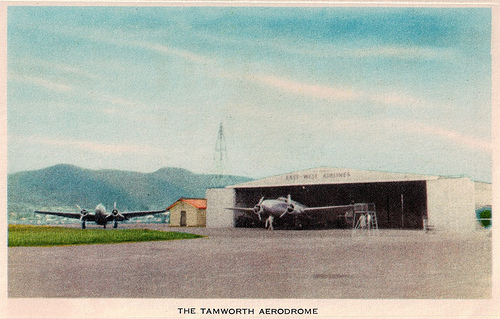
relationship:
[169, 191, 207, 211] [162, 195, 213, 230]
roof on building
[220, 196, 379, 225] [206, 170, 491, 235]
plane in hanger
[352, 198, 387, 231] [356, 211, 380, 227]
ladder by people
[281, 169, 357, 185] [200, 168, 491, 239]
letters are on hangar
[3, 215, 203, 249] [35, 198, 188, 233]
grass in front of plane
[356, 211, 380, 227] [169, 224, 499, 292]
people are on runway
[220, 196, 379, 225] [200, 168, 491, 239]
plane in hangar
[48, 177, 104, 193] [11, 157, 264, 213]
trees are on hills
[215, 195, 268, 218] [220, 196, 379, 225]
left wing on plane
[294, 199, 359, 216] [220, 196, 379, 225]
right wing on plane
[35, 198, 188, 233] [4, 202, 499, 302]
plane on runway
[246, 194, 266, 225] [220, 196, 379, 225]
propeller blade on plane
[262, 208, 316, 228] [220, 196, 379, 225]
underside of plane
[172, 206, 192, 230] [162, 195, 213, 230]
door on building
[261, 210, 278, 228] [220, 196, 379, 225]
person under plane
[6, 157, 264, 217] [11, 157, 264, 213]
hills in background hills